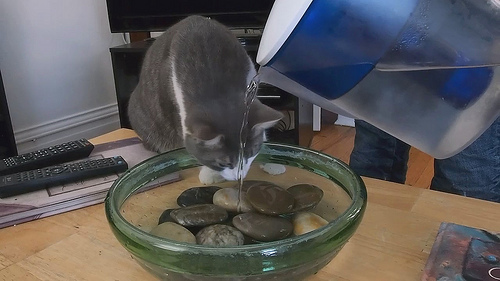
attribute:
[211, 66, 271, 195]
water — pouring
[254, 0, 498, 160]
pitcher — full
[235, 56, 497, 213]
water — poured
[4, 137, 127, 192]
remotes — black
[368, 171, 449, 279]
table — light wood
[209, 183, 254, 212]
rock — gray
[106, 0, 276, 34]
television — black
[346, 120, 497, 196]
legs — covered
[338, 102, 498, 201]
jeans — blue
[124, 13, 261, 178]
cat — grey, fluffy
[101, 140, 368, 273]
bowl — glass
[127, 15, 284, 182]
cat — leaning, grey, white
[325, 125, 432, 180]
floor — hardwood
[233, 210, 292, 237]
rock — gray